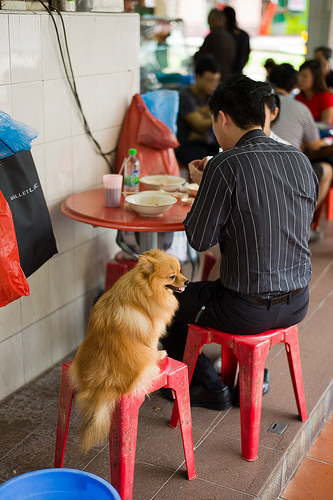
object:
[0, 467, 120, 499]
container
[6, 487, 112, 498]
water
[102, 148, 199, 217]
table food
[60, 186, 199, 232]
table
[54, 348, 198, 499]
red chair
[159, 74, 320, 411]
guy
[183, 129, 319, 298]
shirt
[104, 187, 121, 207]
drink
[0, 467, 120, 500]
bucket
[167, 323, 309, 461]
stool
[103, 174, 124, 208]
cup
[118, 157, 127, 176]
straw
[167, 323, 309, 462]
red stool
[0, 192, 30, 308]
bag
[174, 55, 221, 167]
person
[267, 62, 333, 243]
person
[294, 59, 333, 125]
person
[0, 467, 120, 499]
blue object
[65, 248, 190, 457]
dog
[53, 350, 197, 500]
stool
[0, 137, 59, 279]
bag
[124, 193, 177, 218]
white bowls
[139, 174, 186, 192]
white bowls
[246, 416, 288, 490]
curb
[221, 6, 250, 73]
person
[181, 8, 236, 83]
person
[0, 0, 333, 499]
restaurant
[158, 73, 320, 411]
couple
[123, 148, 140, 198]
bottle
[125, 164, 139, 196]
water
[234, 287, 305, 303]
belt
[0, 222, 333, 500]
ground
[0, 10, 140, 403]
wall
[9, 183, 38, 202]
writing